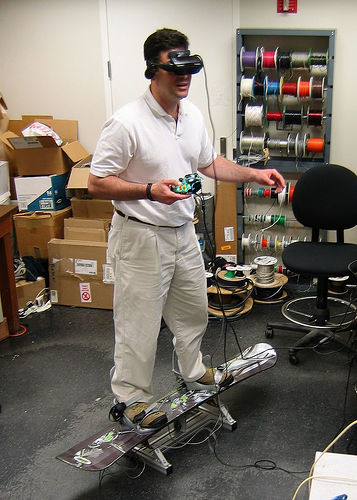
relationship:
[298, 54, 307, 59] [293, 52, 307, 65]
wire on spool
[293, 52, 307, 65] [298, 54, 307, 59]
spool has wire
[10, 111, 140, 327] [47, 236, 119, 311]
collection has box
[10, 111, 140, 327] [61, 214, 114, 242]
collection has box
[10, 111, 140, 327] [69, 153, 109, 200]
collection has box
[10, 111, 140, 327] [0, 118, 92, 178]
collection has box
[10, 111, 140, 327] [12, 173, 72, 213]
collection has box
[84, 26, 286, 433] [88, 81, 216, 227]
man wearing white shirt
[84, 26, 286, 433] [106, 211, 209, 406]
man has pants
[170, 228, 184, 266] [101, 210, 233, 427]
zipper in pants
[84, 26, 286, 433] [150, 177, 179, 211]
man has hand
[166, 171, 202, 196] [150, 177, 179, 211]
game controller in hand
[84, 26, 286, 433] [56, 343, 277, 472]
man on skateboard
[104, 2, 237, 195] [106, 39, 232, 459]
door behind man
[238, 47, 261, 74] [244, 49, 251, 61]
spool has wire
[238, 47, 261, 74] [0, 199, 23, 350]
spool in cabinet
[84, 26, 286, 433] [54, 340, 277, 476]
man on snowboard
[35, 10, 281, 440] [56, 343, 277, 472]
man standing skateboard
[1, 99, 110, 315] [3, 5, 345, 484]
boxes in office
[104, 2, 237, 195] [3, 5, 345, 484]
door leading into office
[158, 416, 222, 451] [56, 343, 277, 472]
wire leading from skateboard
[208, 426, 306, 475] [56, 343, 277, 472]
wire leading from skateboard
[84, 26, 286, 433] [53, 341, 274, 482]
man playing snowboarding game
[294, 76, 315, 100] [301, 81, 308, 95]
spool of wire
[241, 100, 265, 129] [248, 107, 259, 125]
spool of wire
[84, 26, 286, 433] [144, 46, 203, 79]
man wearing face gear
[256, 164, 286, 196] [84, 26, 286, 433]
hand of man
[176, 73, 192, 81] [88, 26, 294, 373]
nose of man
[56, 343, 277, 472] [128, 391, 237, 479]
skateboard placed on frame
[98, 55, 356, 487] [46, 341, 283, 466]
cables running from gadget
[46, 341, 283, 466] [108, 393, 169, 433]
gadget on feet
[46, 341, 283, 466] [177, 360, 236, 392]
gadget on feet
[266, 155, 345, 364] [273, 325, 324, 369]
chair with wheels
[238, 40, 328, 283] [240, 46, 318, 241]
rolls of cables